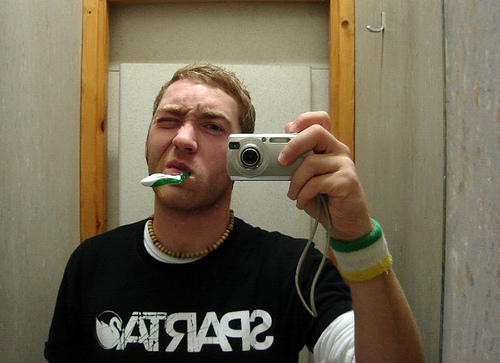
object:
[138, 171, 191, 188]
toothbrush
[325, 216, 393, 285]
wristband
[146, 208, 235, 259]
necklace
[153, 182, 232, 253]
neck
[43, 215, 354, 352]
shirt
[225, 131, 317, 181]
camera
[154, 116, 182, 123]
eye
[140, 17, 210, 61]
door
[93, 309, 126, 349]
logo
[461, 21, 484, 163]
wall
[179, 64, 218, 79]
hair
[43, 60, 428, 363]
man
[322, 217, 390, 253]
wrist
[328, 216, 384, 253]
band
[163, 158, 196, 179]
mouth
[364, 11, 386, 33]
handle